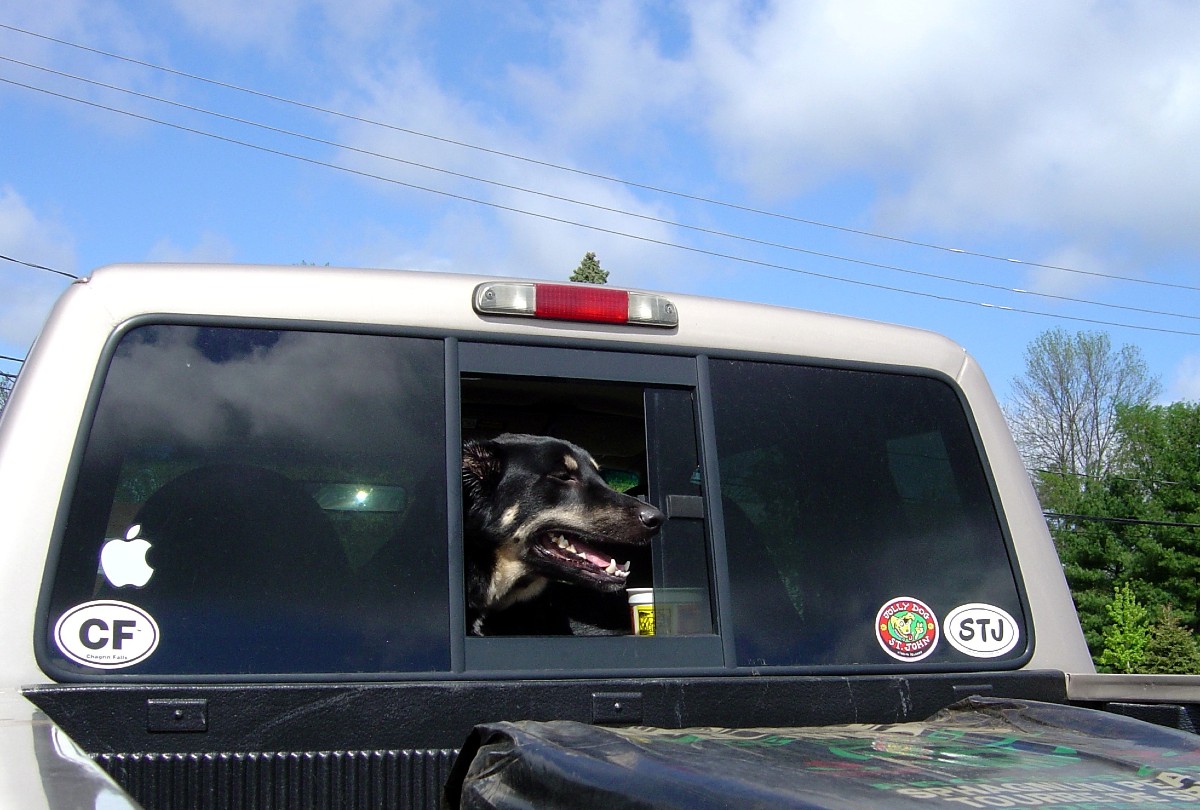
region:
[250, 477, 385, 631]
the window of this car are tinted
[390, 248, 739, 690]
Dog enjoying the breeze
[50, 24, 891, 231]
Clear blue sky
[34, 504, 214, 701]
Popular logos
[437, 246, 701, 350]
Truck brake light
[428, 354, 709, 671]
Dog taking a car ride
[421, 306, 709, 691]
Dog smelling the fresh air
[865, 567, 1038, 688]
Bumper stickers on a truck window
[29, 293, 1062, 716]
Tinted rear window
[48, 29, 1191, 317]
Telephone lines streaking through the sky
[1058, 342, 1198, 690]
Lush Evergreen trees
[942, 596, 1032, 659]
There's a STJ sticker on the glass.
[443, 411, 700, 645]
The dog is black and brown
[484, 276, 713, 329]
There's red light on the top of the truck.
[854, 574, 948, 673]
The sticker is green and red.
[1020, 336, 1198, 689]
There are trees on the side of the truck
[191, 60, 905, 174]
The sky is blue and white.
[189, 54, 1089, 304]
There are three electric lines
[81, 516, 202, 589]
There's apple logo on the glass.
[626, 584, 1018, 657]
the tint of the truck is black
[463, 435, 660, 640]
the dog has pink tongue.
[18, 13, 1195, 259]
the sky is blue with clouds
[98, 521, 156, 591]
Apple decal in truck window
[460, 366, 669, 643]
dog looking out open back window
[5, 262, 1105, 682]
cab area of white truck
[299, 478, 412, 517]
truck mirror reflecting a light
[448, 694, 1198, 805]
large container with plastic tarp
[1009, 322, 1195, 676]
trees and shrubbery in the distance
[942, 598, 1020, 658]
decal with the letters STJ on it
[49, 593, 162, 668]
decal with the letters CF on it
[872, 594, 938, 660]
red and green decal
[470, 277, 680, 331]
brake light on top of truck cab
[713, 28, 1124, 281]
White puffy clouds in the sky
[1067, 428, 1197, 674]
Green leaves on the trees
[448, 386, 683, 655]
A dog is looking out the window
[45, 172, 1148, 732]
A white truck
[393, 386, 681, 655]
A dog is black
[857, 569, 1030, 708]
Stickers on the back window of a truck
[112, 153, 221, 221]
The sky is light blue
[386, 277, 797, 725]
A window is open on the truck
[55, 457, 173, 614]
A white Apple sticker on the window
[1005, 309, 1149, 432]
No leaves on tree branches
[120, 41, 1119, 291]
Light, blue sky and thin, white fleecy clouds.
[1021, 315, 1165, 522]
Tree with bare branches.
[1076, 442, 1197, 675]
Healthy, green evergreen trees.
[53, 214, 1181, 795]
Rear view of white pickup truck.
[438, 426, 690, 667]
Head of black and white dog.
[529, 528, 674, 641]
Open mouth of dog, showing teeth.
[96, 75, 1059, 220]
Telephone wires, cutting across sky.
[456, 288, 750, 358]
Emergency, red and white light.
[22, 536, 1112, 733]
Three decals on back windows, including bitten apple.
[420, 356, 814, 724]
Center portion of back window open, for air for dog.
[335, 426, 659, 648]
German Shepard dog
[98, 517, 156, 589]
Apple logo window decal sticker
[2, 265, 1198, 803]
back of silver truck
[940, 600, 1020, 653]
window decal that says STJ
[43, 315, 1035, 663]
tinted back windshield of silver truck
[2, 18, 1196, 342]
three power lines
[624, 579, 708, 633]
yellow and white soft drink cup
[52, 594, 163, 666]
white window decal that says CF